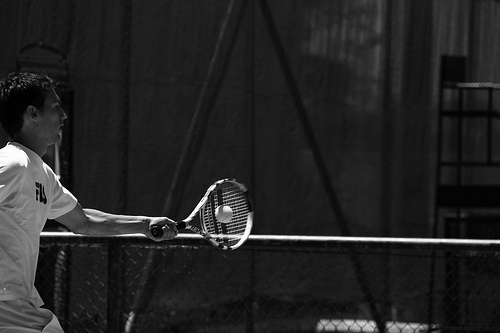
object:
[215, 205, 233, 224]
ball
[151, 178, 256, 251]
racket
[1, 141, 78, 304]
shirt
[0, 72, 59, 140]
hair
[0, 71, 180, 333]
man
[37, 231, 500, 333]
net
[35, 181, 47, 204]
logo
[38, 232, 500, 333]
fence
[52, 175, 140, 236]
arm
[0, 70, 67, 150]
head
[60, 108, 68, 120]
nose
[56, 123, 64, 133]
mouth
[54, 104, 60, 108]
eye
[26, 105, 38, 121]
ear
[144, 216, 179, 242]
hand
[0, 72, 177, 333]
player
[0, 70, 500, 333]
court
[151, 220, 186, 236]
handle